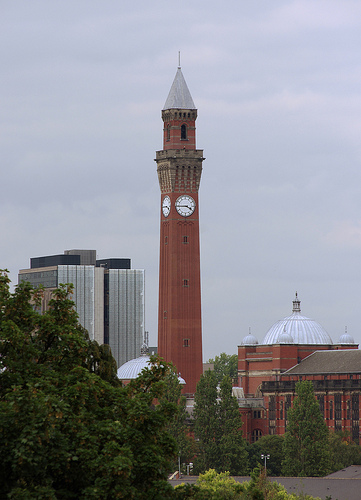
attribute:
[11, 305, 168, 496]
trees — green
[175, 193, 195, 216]
clock — white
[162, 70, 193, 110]
tower — grey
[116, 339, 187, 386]
dome — white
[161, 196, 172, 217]
clock — large, black, white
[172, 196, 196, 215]
clock — large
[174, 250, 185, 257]
brick — red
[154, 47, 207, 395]
tower — large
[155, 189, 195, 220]
clock — tall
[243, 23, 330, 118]
thick clouds — grey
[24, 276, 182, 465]
trees — green, leafy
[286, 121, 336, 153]
sky — grey, cloudy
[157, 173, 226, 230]
clock — large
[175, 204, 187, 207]
hand — black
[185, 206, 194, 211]
hand — black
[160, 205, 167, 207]
hand — black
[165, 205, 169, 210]
hand — black